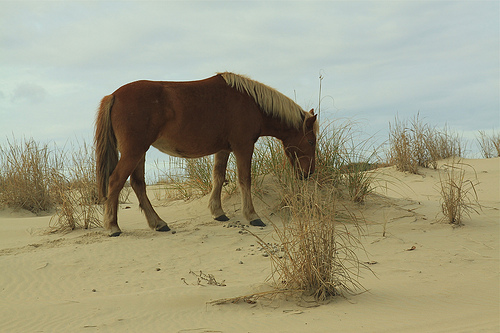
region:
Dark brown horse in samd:
[77, 56, 354, 248]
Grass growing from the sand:
[263, 176, 364, 324]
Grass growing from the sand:
[430, 160, 475, 231]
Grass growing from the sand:
[337, 125, 380, 211]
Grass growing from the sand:
[373, 127, 458, 178]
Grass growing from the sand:
[50, 160, 127, 227]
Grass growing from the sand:
[1, 118, 86, 247]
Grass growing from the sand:
[55, 132, 130, 266]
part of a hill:
[439, 210, 458, 232]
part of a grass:
[316, 263, 323, 282]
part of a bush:
[303, 253, 314, 271]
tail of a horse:
[101, 140, 108, 150]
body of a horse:
[211, 112, 232, 147]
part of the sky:
[355, 85, 377, 115]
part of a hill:
[399, 169, 406, 174]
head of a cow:
[310, 138, 315, 147]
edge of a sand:
[431, 247, 445, 275]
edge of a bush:
[300, 253, 317, 290]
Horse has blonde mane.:
[231, 72, 318, 129]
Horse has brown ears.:
[301, 99, 316, 126]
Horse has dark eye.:
[298, 130, 329, 159]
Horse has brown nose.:
[284, 155, 326, 192]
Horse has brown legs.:
[98, 159, 269, 186]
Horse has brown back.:
[129, 70, 195, 106]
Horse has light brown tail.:
[75, 86, 140, 208]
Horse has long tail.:
[81, 82, 139, 224]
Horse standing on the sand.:
[126, 180, 292, 246]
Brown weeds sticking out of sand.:
[254, 189, 366, 316]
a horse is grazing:
[53, 36, 346, 248]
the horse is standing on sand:
[78, 38, 470, 311]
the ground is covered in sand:
[20, 153, 486, 317]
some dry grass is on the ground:
[253, 148, 358, 305]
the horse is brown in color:
[71, 59, 385, 254]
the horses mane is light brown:
[219, 66, 321, 128]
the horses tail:
[93, 88, 120, 223]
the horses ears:
[297, 93, 322, 137]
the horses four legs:
[88, 140, 273, 243]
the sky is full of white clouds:
[14, 5, 484, 97]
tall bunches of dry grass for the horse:
[241, 158, 357, 308]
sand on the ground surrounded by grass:
[41, 244, 136, 331]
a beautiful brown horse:
[76, 42, 356, 249]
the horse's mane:
[207, 55, 314, 132]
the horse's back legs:
[101, 154, 185, 250]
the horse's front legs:
[206, 143, 261, 241]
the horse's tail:
[81, 71, 126, 209]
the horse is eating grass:
[286, 87, 331, 179]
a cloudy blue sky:
[344, 28, 467, 118]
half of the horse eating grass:
[179, 30, 349, 234]